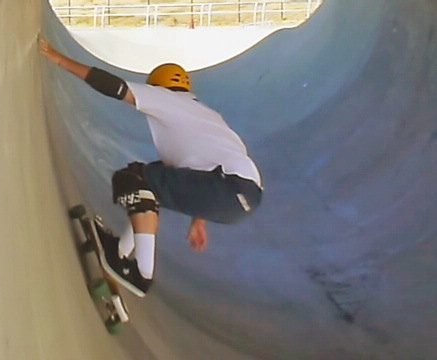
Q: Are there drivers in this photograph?
A: No, there are no drivers.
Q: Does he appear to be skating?
A: Yes, the man is skating.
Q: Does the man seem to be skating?
A: Yes, the man is skating.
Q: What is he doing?
A: The man is skating.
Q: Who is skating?
A: The man is skating.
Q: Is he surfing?
A: No, the man is skating.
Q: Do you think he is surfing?
A: No, the man is skating.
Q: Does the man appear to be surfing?
A: No, the man is skating.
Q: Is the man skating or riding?
A: The man is skating.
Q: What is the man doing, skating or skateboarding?
A: The man is skating.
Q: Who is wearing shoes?
A: The man is wearing shoes.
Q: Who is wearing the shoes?
A: The man is wearing shoes.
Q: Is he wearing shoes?
A: Yes, the man is wearing shoes.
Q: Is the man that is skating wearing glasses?
A: No, the man is wearing shoes.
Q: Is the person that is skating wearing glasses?
A: No, the man is wearing shoes.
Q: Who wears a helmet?
A: The man wears a helmet.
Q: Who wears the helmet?
A: The man wears a helmet.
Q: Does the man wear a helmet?
A: Yes, the man wears a helmet.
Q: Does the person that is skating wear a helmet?
A: Yes, the man wears a helmet.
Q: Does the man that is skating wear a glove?
A: No, the man wears a helmet.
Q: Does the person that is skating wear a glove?
A: No, the man wears a helmet.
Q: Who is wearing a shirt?
A: The man is wearing a shirt.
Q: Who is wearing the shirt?
A: The man is wearing a shirt.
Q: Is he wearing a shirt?
A: Yes, the man is wearing a shirt.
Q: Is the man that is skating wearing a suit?
A: No, the man is wearing a shirt.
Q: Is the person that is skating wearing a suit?
A: No, the man is wearing a shirt.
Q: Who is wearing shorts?
A: The man is wearing shorts.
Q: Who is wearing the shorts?
A: The man is wearing shorts.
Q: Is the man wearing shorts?
A: Yes, the man is wearing shorts.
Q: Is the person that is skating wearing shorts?
A: Yes, the man is wearing shorts.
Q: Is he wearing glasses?
A: No, the man is wearing shorts.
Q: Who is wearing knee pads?
A: The man is wearing knee pads.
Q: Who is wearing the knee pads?
A: The man is wearing knee pads.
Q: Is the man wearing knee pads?
A: Yes, the man is wearing knee pads.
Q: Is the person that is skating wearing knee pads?
A: Yes, the man is wearing knee pads.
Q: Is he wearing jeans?
A: No, the man is wearing knee pads.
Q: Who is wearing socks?
A: The man is wearing socks.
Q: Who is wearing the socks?
A: The man is wearing socks.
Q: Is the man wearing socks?
A: Yes, the man is wearing socks.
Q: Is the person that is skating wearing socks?
A: Yes, the man is wearing socks.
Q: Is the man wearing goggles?
A: No, the man is wearing socks.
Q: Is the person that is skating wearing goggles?
A: No, the man is wearing socks.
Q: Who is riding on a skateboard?
A: The man is riding on a skateboard.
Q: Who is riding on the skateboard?
A: The man is riding on a skateboard.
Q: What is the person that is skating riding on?
A: The man is riding on a skateboard.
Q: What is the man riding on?
A: The man is riding on a skateboard.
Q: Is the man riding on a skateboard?
A: Yes, the man is riding on a skateboard.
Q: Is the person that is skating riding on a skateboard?
A: Yes, the man is riding on a skateboard.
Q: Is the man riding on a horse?
A: No, the man is riding on a skateboard.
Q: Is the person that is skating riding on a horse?
A: No, the man is riding on a skateboard.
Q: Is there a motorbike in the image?
A: No, there are no motorcycles.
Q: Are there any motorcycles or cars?
A: No, there are no motorcycles or cars.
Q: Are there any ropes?
A: No, there are no ropes.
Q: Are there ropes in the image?
A: No, there are no ropes.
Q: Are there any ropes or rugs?
A: No, there are no ropes or rugs.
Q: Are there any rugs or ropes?
A: No, there are no ropes or rugs.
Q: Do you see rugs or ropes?
A: No, there are no ropes or rugs.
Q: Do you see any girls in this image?
A: No, there are no girls.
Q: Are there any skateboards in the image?
A: Yes, there is a skateboard.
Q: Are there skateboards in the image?
A: Yes, there is a skateboard.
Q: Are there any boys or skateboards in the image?
A: Yes, there is a skateboard.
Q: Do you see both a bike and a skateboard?
A: No, there is a skateboard but no bikes.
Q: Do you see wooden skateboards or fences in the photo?
A: Yes, there is a wood skateboard.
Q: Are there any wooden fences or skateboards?
A: Yes, there is a wood skateboard.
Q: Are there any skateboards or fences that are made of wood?
A: Yes, the skateboard is made of wood.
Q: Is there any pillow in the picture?
A: No, there are no pillows.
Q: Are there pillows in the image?
A: No, there are no pillows.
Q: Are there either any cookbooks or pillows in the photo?
A: No, there are no pillows or cookbooks.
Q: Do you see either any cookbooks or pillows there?
A: No, there are no pillows or cookbooks.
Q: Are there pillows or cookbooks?
A: No, there are no pillows or cookbooks.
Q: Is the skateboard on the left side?
A: Yes, the skateboard is on the left of the image.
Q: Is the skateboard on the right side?
A: No, the skateboard is on the left of the image.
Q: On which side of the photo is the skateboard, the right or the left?
A: The skateboard is on the left of the image.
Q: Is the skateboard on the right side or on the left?
A: The skateboard is on the left of the image.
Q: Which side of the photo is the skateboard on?
A: The skateboard is on the left of the image.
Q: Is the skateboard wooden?
A: Yes, the skateboard is wooden.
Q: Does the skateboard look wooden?
A: Yes, the skateboard is wooden.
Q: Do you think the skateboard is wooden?
A: Yes, the skateboard is wooden.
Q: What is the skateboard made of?
A: The skateboard is made of wood.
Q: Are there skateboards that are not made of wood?
A: No, there is a skateboard but it is made of wood.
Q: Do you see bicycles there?
A: No, there are no bicycles.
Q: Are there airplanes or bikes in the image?
A: No, there are no bikes or airplanes.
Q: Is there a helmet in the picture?
A: Yes, there is a helmet.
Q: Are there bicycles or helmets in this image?
A: Yes, there is a helmet.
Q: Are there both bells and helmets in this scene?
A: No, there is a helmet but no bells.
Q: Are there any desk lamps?
A: No, there are no desk lamps.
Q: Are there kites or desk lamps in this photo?
A: No, there are no desk lamps or kites.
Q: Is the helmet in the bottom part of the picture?
A: No, the helmet is in the top of the image.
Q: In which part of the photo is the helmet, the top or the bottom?
A: The helmet is in the top of the image.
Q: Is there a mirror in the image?
A: No, there are no mirrors.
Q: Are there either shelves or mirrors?
A: No, there are no mirrors or shelves.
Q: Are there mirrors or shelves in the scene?
A: No, there are no mirrors or shelves.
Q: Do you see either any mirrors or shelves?
A: No, there are no mirrors or shelves.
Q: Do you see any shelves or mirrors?
A: No, there are no mirrors or shelves.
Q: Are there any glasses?
A: No, there are no glasses.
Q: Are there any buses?
A: No, there are no buses.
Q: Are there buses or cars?
A: No, there are no buses or cars.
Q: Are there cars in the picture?
A: No, there are no cars.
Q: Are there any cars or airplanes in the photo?
A: No, there are no cars or airplanes.